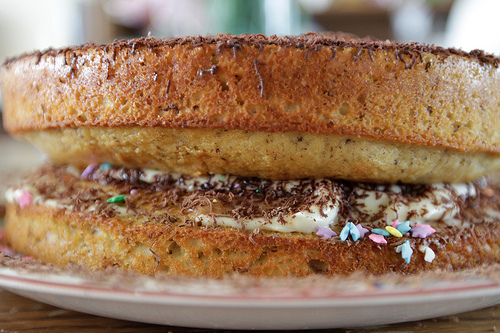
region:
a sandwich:
[58, 61, 498, 278]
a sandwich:
[78, 89, 365, 326]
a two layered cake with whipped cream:
[1, 21, 493, 292]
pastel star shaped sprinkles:
[318, 221, 455, 290]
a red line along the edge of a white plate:
[279, 285, 346, 317]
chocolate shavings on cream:
[180, 177, 329, 234]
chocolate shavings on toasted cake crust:
[170, 43, 306, 122]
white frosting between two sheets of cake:
[291, 211, 312, 226]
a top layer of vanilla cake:
[55, 35, 458, 155]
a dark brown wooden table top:
[1, 300, 47, 330]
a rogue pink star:
[14, 188, 35, 210]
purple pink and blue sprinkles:
[318, 215, 443, 275]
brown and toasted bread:
[45, 51, 469, 161]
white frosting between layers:
[82, 150, 465, 232]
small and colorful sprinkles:
[316, 224, 431, 268]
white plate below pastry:
[20, 259, 454, 312]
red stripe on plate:
[27, 271, 436, 313]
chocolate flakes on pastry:
[5, 160, 370, 217]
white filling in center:
[58, 145, 425, 242]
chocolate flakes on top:
[39, 46, 311, 110]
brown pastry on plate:
[11, 48, 491, 289]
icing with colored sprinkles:
[1, 171, 225, 205]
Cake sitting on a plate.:
[2, 40, 491, 288]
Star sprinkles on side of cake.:
[307, 221, 452, 269]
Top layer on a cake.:
[5, 37, 492, 177]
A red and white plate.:
[0, 278, 498, 323]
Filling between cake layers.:
[27, 153, 485, 233]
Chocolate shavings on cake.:
[16, 27, 493, 52]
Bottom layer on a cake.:
[10, 214, 498, 284]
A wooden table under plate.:
[0, 291, 52, 331]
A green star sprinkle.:
[100, 187, 133, 204]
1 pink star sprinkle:
[10, 191, 37, 211]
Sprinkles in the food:
[315, 217, 440, 269]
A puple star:
[310, 211, 336, 246]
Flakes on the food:
[91, 180, 246, 241]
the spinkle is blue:
[397, 241, 415, 262]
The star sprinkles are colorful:
[329, 209, 452, 279]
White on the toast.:
[265, 206, 309, 236]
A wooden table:
[1, 310, 59, 332]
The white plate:
[12, 275, 379, 331]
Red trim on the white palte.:
[17, 268, 498, 293]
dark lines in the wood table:
[6, 308, 53, 332]